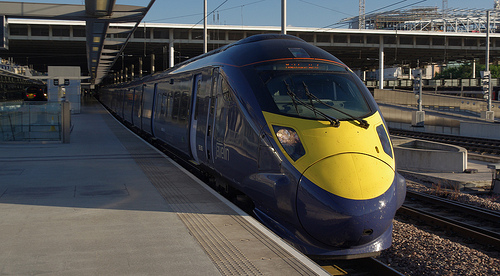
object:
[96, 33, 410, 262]
train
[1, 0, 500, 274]
station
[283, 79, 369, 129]
wipers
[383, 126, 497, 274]
tracks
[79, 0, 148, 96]
awning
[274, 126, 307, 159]
headlight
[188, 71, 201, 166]
door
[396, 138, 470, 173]
pillar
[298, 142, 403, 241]
nose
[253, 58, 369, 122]
windsheild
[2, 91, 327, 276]
walkway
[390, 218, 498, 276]
gravel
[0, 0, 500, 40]
sky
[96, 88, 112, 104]
lights